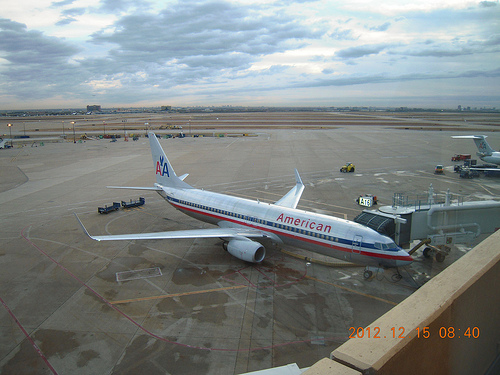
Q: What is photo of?
A: Airplane.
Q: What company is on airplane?
A: American.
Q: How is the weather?
A: Cloudy.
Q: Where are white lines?
A: On ground.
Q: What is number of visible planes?
A: Two.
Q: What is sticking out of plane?
A: Two wings.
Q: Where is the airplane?
A: On tarmac near the terminal.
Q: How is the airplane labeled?
A: American.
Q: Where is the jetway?
A: Left front of the plane.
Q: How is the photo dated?
A: 12-15-2012.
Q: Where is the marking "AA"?
A: Tail fin of the plane.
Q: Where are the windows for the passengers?
A: Beneath the blue stripe.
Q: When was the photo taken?
A: 8:40 AM.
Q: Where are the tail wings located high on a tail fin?
A: Airplane on the right.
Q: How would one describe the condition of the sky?
A: Completely cloudy.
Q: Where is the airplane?
A: Sitting at airport.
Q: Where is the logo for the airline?
A: On tail section.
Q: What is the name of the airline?
A: American.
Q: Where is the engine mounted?
A: On the wing.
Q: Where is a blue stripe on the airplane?
A: First stripe around the airplane.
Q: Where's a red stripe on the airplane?
A: Under the blue stripe.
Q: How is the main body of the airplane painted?
A: Silver.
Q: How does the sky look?
A: Grey and blue clouds.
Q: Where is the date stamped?
A: Right hand corner.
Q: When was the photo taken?
A: Daytime.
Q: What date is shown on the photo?
A: 12-15-2012.